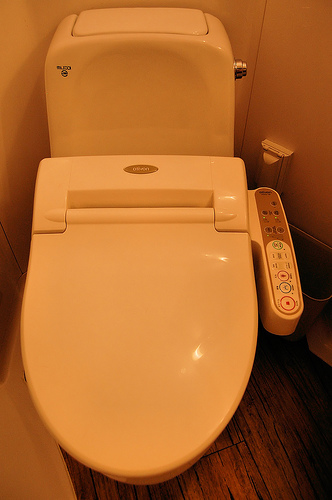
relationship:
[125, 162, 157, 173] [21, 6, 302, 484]
emblem on toilet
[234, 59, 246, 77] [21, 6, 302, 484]
chrome button on toilet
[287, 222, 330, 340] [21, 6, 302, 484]
waste basket by toilet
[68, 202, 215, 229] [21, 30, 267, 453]
hinge on toilet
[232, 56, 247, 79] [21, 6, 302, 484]
flusher on toilet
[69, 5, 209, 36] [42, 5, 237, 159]
opening to tank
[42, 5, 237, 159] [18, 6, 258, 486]
tank of toilet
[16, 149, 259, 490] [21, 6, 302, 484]
seat of toilet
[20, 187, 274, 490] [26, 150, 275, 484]
lid on toilet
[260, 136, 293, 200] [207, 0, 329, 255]
outlet on wall